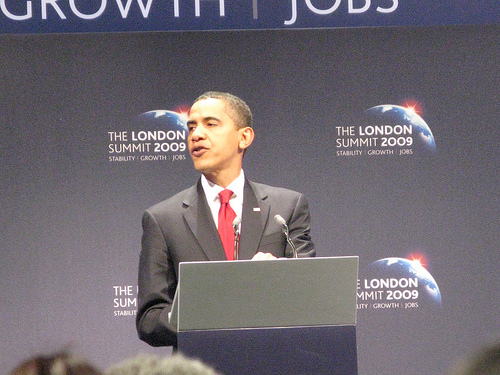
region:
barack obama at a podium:
[132, 79, 358, 374]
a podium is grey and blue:
[161, 258, 362, 373]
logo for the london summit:
[332, 99, 436, 168]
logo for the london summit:
[358, 251, 443, 318]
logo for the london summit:
[101, 106, 185, 166]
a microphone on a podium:
[270, 213, 299, 259]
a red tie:
[210, 190, 240, 261]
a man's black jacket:
[138, 177, 313, 344]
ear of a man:
[236, 124, 254, 149]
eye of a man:
[204, 118, 217, 128]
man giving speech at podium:
[127, 85, 374, 374]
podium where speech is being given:
[171, 206, 366, 372]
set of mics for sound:
[231, 208, 302, 260]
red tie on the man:
[211, 188, 240, 261]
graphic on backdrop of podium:
[322, 93, 447, 165]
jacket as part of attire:
[135, 179, 322, 331]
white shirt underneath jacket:
[195, 175, 244, 222]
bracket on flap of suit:
[248, 205, 265, 217]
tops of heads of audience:
[0, 342, 230, 374]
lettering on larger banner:
[1, 0, 492, 38]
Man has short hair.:
[189, 85, 278, 132]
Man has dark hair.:
[181, 80, 283, 143]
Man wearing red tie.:
[196, 185, 269, 233]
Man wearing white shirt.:
[211, 175, 243, 213]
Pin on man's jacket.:
[242, 198, 264, 214]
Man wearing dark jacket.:
[136, 185, 336, 286]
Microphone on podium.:
[274, 209, 327, 279]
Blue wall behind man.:
[51, 52, 424, 351]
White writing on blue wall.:
[330, 113, 417, 161]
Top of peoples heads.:
[34, 343, 223, 373]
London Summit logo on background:
[311, 83, 451, 188]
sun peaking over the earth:
[403, 100, 423, 115]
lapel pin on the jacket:
[248, 203, 262, 213]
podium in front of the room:
[153, 254, 410, 369]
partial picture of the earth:
[368, 99, 439, 160]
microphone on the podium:
[271, 212, 300, 257]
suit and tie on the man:
[124, 174, 339, 279]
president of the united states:
[126, 83, 319, 258]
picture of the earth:
[377, 78, 438, 163]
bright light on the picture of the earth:
[405, 245, 435, 273]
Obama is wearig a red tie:
[203, 181, 249, 259]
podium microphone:
[256, 209, 325, 267]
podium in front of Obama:
[156, 231, 404, 372]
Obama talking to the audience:
[181, 86, 249, 179]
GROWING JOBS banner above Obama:
[5, 4, 496, 36]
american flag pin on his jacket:
[249, 202, 266, 215]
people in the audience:
[10, 346, 239, 373]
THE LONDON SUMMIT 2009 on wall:
[340, 119, 434, 159]